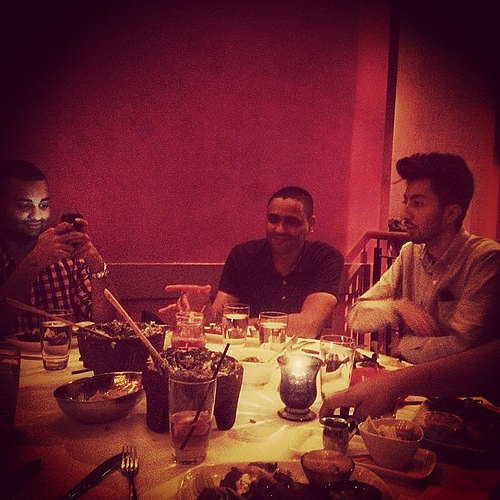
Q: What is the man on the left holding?
A: A phone.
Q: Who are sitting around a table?
A: Males.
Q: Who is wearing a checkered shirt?
A: A young man.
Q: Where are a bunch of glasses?
A: On the table.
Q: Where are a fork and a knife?
A: Over the table.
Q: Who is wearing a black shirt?
A: A man.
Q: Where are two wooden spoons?
A: On bowls.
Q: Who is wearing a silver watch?
A: Man with cell phone.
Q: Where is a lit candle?
A: In a vase.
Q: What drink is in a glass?
A: Water.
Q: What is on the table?
A: Drinking glasses.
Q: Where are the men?
A: Table.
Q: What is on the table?
A: A hand.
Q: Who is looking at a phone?
A: A man.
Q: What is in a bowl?
A: A spoon.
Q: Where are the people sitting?
A: A table.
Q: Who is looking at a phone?
A: A man.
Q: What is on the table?
A: Salad bowl.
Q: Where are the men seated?
A: A table.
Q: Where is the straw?
A: On table.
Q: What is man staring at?
A: Screen.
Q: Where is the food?
A: In bowl.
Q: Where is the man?
A: At table.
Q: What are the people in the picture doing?
A: Sharing a meal.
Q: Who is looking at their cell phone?
A: The person on the left.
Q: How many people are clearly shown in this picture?
A: Three.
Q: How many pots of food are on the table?
A: Two.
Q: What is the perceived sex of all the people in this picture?
A: Male.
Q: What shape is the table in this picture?
A: Circular.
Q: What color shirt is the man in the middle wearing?
A: Black.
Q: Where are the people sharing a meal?
A: At restaurant.